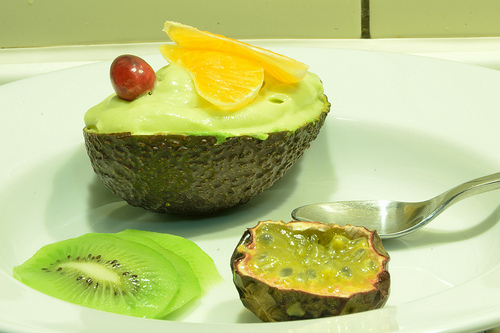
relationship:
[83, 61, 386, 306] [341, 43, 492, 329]
fruits on plate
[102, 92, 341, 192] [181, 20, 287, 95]
avocado have fruit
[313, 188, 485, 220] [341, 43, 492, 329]
spoon in plate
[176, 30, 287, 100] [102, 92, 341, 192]
orange on avocado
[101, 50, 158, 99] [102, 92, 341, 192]
grape on avocado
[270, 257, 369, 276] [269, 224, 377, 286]
seeds in center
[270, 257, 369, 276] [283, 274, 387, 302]
seeds in filling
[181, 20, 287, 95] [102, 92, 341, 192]
fruit on avocado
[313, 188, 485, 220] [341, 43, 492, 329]
spoon on plate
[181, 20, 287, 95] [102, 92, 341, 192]
oranges on fruit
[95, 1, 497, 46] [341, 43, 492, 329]
wall behind plate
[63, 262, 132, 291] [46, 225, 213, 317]
seeds in kiwi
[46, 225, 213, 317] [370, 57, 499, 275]
kiwi in bowl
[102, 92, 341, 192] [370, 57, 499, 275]
avocado in bowl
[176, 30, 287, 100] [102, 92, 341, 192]
orange top of avocado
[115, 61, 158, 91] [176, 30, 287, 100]
cherry next to orange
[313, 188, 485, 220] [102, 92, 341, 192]
spoon next to avocado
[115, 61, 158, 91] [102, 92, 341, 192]
cherry on avocado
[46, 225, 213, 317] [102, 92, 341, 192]
kiwi next to avocado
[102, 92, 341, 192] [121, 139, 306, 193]
avocado has skin